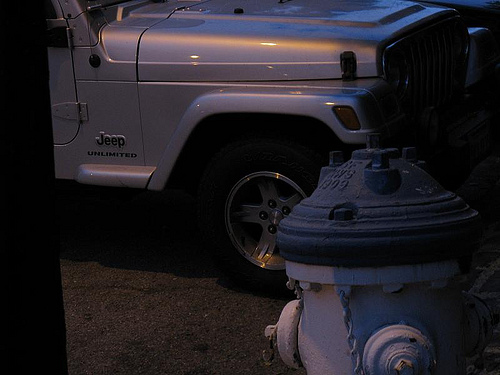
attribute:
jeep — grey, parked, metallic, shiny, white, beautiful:
[2, 3, 495, 291]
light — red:
[328, 97, 363, 136]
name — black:
[82, 129, 144, 164]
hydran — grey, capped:
[248, 133, 480, 375]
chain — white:
[331, 293, 369, 373]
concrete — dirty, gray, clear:
[65, 251, 271, 372]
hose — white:
[353, 318, 446, 375]